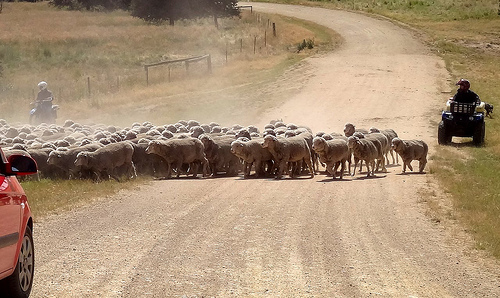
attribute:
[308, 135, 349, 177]
sheep — small, brown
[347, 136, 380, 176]
sheep — brown, small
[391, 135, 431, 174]
sheep — brown, small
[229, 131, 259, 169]
sheep — small, brown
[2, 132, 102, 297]
car — red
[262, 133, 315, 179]
sheep — brown, small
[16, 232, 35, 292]
hubcap — grey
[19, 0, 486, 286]
road — dirt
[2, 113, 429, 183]
sheep herd — large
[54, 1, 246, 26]
leaves — green